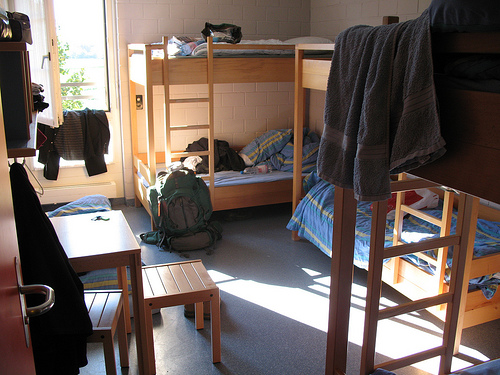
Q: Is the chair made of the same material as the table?
A: Yes, both the chair and the table are made of wood.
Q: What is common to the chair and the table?
A: The material, both the chair and the table are wooden.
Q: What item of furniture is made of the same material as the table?
A: The chair is made of the same material as the table.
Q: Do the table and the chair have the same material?
A: Yes, both the table and the chair are made of wood.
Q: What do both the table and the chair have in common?
A: The material, both the table and the chair are wooden.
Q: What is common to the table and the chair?
A: The material, both the table and the chair are wooden.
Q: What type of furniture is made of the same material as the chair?
A: The table is made of the same material as the chair.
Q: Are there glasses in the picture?
A: No, there are no glasses.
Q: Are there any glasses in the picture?
A: No, there are no glasses.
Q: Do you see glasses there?
A: No, there are no glasses.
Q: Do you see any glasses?
A: No, there are no glasses.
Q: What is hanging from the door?
A: The jacket is hanging from the door.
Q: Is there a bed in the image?
A: Yes, there is a bed.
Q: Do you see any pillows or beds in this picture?
A: Yes, there is a bed.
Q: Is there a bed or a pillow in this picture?
A: Yes, there is a bed.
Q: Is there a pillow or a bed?
A: Yes, there is a bed.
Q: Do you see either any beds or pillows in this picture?
A: Yes, there is a bed.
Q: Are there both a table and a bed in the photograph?
A: Yes, there are both a bed and a table.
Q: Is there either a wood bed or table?
A: Yes, there is a wood bed.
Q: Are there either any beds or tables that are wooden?
A: Yes, the bed is wooden.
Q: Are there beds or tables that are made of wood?
A: Yes, the bed is made of wood.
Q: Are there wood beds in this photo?
A: Yes, there is a wood bed.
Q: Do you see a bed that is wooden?
A: Yes, there is a bed that is wooden.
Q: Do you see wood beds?
A: Yes, there is a bed that is made of wood.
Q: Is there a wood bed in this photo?
A: Yes, there is a bed that is made of wood.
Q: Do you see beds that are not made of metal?
A: Yes, there is a bed that is made of wood.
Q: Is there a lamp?
A: No, there are no lamps.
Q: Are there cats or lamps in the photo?
A: No, there are no lamps or cats.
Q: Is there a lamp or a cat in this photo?
A: No, there are no lamps or cats.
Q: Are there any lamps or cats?
A: No, there are no lamps or cats.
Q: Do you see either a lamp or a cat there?
A: No, there are no lamps or cats.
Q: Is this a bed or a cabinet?
A: This is a bed.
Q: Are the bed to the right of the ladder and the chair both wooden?
A: Yes, both the bed and the chair are wooden.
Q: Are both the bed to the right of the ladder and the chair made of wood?
A: Yes, both the bed and the chair are made of wood.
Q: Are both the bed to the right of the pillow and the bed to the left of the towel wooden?
A: Yes, both the bed and the bed are wooden.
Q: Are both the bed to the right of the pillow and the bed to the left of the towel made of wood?
A: Yes, both the bed and the bed are made of wood.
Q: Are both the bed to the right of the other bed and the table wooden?
A: Yes, both the bed and the table are wooden.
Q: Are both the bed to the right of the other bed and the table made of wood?
A: Yes, both the bed and the table are made of wood.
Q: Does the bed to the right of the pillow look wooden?
A: Yes, the bed is wooden.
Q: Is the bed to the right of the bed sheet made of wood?
A: Yes, the bed is made of wood.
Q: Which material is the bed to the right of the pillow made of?
A: The bed is made of wood.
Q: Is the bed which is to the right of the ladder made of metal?
A: No, the bed is made of wood.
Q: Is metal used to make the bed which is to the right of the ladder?
A: No, the bed is made of wood.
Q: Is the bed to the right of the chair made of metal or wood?
A: The bed is made of wood.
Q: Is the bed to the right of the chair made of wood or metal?
A: The bed is made of wood.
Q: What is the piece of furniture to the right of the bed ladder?
A: The piece of furniture is a bed.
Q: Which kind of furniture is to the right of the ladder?
A: The piece of furniture is a bed.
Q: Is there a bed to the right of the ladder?
A: Yes, there is a bed to the right of the ladder.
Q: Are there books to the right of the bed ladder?
A: No, there is a bed to the right of the ladder.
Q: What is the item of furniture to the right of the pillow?
A: The piece of furniture is a bed.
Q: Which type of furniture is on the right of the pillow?
A: The piece of furniture is a bed.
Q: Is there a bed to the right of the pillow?
A: Yes, there is a bed to the right of the pillow.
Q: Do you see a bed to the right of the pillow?
A: Yes, there is a bed to the right of the pillow.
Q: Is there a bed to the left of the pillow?
A: No, the bed is to the right of the pillow.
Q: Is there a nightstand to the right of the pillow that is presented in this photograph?
A: No, there is a bed to the right of the pillow.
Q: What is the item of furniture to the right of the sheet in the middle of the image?
A: The piece of furniture is a bed.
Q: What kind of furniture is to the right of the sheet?
A: The piece of furniture is a bed.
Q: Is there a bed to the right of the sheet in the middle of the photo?
A: Yes, there is a bed to the right of the bed sheet.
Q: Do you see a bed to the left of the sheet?
A: No, the bed is to the right of the sheet.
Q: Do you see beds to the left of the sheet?
A: No, the bed is to the right of the sheet.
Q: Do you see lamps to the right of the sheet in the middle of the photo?
A: No, there is a bed to the right of the sheet.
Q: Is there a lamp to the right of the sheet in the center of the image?
A: No, there is a bed to the right of the sheet.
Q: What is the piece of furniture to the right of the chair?
A: The piece of furniture is a bed.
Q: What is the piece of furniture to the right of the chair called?
A: The piece of furniture is a bed.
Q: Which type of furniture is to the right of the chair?
A: The piece of furniture is a bed.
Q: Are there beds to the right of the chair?
A: Yes, there is a bed to the right of the chair.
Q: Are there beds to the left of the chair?
A: No, the bed is to the right of the chair.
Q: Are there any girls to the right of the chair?
A: No, there is a bed to the right of the chair.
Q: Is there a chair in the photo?
A: Yes, there is a chair.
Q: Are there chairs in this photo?
A: Yes, there is a chair.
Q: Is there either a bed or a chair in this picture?
A: Yes, there is a chair.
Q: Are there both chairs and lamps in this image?
A: No, there is a chair but no lamps.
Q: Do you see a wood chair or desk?
A: Yes, there is a wood chair.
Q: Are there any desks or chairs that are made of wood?
A: Yes, the chair is made of wood.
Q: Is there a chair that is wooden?
A: Yes, there is a wood chair.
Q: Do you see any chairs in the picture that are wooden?
A: Yes, there is a chair that is wooden.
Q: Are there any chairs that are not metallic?
A: Yes, there is a wooden chair.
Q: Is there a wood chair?
A: Yes, there is a chair that is made of wood.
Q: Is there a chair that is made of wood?
A: Yes, there is a chair that is made of wood.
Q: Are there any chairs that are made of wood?
A: Yes, there is a chair that is made of wood.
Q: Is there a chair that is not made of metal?
A: Yes, there is a chair that is made of wood.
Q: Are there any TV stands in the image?
A: No, there are no TV stands.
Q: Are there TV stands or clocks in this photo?
A: No, there are no TV stands or clocks.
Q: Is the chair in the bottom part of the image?
A: Yes, the chair is in the bottom of the image.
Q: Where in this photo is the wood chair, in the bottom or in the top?
A: The chair is in the bottom of the image.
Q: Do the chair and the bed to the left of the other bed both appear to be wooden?
A: Yes, both the chair and the bed are wooden.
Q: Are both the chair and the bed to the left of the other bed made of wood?
A: Yes, both the chair and the bed are made of wood.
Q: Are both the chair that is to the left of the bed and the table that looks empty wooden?
A: Yes, both the chair and the table are wooden.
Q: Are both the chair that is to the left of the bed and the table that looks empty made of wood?
A: Yes, both the chair and the table are made of wood.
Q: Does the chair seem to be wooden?
A: Yes, the chair is wooden.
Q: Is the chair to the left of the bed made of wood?
A: Yes, the chair is made of wood.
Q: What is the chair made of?
A: The chair is made of wood.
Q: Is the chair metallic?
A: No, the chair is wooden.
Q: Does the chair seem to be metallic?
A: No, the chair is wooden.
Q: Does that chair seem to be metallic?
A: No, the chair is wooden.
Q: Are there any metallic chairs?
A: No, there is a chair but it is wooden.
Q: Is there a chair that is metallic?
A: No, there is a chair but it is wooden.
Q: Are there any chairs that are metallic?
A: No, there is a chair but it is wooden.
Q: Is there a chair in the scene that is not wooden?
A: No, there is a chair but it is wooden.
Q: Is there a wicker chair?
A: No, there is a chair but it is made of wood.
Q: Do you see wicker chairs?
A: No, there is a chair but it is made of wood.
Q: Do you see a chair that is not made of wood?
A: No, there is a chair but it is made of wood.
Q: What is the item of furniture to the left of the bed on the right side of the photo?
A: The piece of furniture is a chair.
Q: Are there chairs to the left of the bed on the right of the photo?
A: Yes, there is a chair to the left of the bed.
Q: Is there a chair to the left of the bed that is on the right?
A: Yes, there is a chair to the left of the bed.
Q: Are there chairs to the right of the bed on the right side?
A: No, the chair is to the left of the bed.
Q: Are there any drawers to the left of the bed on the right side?
A: No, there is a chair to the left of the bed.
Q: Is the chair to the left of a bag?
A: No, the chair is to the left of the bed.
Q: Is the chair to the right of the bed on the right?
A: No, the chair is to the left of the bed.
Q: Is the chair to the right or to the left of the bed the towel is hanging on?
A: The chair is to the left of the bed.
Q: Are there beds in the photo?
A: Yes, there is a bed.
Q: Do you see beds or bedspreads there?
A: Yes, there is a bed.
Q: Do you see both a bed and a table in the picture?
A: Yes, there are both a bed and a table.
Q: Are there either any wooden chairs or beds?
A: Yes, there is a wood bed.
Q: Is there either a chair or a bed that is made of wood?
A: Yes, the bed is made of wood.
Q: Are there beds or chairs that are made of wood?
A: Yes, the bed is made of wood.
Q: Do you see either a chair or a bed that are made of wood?
A: Yes, the bed is made of wood.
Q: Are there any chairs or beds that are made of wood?
A: Yes, the bed is made of wood.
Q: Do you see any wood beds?
A: Yes, there is a bed that is made of wood.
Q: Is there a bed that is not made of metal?
A: Yes, there is a bed that is made of wood.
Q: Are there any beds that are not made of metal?
A: Yes, there is a bed that is made of wood.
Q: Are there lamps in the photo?
A: No, there are no lamps.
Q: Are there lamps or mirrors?
A: No, there are no lamps or mirrors.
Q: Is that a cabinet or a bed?
A: That is a bed.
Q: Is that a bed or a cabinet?
A: That is a bed.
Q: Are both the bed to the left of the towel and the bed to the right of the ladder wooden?
A: Yes, both the bed and the bed are wooden.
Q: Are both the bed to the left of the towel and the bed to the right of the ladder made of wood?
A: Yes, both the bed and the bed are made of wood.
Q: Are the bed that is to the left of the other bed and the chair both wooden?
A: Yes, both the bed and the chair are wooden.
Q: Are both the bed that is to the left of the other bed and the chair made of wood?
A: Yes, both the bed and the chair are made of wood.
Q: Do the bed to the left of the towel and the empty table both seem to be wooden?
A: Yes, both the bed and the table are wooden.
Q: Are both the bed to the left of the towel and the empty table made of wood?
A: Yes, both the bed and the table are made of wood.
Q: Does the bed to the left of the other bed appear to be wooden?
A: Yes, the bed is wooden.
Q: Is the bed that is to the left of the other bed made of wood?
A: Yes, the bed is made of wood.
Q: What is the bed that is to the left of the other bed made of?
A: The bed is made of wood.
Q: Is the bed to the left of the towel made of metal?
A: No, the bed is made of wood.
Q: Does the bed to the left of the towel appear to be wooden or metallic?
A: The bed is wooden.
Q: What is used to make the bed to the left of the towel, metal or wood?
A: The bed is made of wood.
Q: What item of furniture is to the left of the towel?
A: The piece of furniture is a bed.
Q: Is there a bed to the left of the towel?
A: Yes, there is a bed to the left of the towel.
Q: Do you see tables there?
A: Yes, there is a table.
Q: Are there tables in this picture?
A: Yes, there is a table.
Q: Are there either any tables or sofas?
A: Yes, there is a table.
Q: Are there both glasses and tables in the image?
A: No, there is a table but no glasses.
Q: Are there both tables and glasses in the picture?
A: No, there is a table but no glasses.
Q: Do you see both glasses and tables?
A: No, there is a table but no glasses.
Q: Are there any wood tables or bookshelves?
A: Yes, there is a wood table.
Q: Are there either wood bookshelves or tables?
A: Yes, there is a wood table.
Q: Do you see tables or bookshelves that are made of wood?
A: Yes, the table is made of wood.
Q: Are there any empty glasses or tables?
A: Yes, there is an empty table.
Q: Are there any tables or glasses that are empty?
A: Yes, the table is empty.